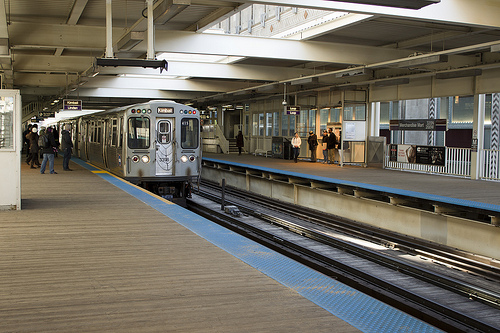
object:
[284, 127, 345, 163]
people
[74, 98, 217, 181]
train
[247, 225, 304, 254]
tracks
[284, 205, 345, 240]
tracks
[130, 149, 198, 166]
headlights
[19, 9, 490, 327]
station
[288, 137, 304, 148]
shirt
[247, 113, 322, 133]
windows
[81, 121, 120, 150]
windows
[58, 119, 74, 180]
person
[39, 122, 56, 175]
person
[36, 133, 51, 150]
backpack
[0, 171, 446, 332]
floor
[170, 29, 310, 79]
rafters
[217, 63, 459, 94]
pipe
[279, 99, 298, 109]
light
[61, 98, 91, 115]
sign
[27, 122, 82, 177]
people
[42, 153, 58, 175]
jeans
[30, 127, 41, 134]
hat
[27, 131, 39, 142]
hair